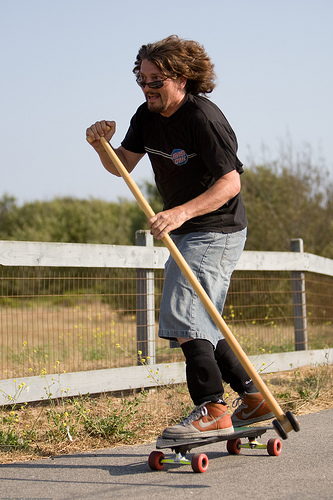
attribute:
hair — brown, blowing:
[133, 37, 214, 97]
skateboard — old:
[149, 423, 281, 472]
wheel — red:
[268, 438, 282, 456]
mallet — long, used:
[100, 137, 298, 438]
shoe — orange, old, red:
[165, 403, 234, 439]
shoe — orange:
[232, 392, 277, 425]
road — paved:
[0, 413, 330, 499]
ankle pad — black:
[182, 341, 225, 404]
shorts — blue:
[158, 224, 249, 345]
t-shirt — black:
[121, 93, 248, 233]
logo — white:
[144, 145, 197, 166]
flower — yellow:
[137, 350, 145, 358]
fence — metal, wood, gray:
[2, 231, 333, 404]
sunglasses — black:
[138, 74, 172, 88]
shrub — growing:
[2, 199, 144, 294]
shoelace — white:
[174, 405, 207, 425]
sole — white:
[166, 427, 235, 437]